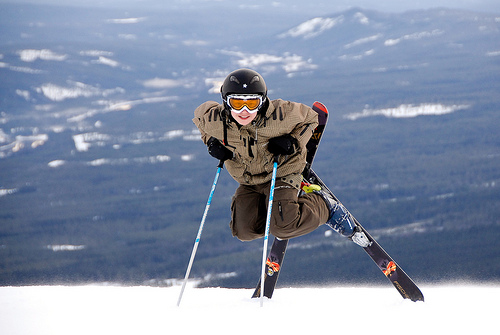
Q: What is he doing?
A: Snowskating.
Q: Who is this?
A: A man.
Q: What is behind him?
A: Mountains.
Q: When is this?
A: Daytime.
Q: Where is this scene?
A: On a ski slope.